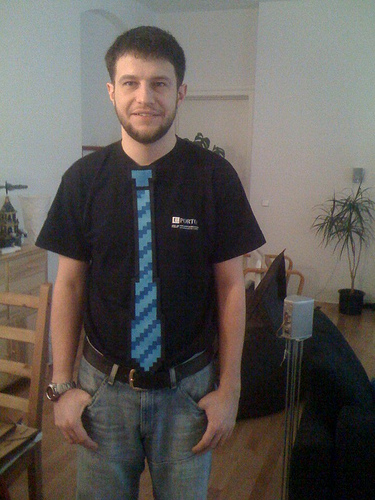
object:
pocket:
[181, 385, 219, 451]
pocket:
[73, 376, 109, 451]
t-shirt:
[32, 133, 264, 366]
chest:
[0, 241, 52, 387]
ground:
[315, 98, 327, 111]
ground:
[255, 153, 268, 174]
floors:
[210, 411, 299, 500]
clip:
[129, 369, 148, 391]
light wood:
[0, 283, 51, 497]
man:
[32, 26, 266, 494]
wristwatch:
[44, 379, 76, 403]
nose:
[136, 79, 155, 105]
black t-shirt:
[35, 134, 268, 376]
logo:
[171, 215, 200, 231]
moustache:
[131, 104, 163, 114]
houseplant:
[307, 172, 375, 315]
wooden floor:
[1, 297, 372, 497]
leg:
[74, 352, 146, 498]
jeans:
[73, 335, 215, 500]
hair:
[104, 26, 187, 90]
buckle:
[128, 367, 167, 390]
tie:
[131, 167, 165, 372]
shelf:
[1, 282, 54, 428]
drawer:
[8, 251, 50, 282]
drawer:
[7, 286, 43, 320]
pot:
[337, 288, 363, 316]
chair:
[0, 282, 53, 499]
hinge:
[129, 369, 148, 392]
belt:
[80, 336, 215, 389]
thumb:
[84, 394, 92, 406]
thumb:
[197, 395, 207, 410]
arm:
[210, 167, 247, 394]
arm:
[48, 172, 89, 392]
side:
[83, 188, 103, 353]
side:
[201, 175, 219, 352]